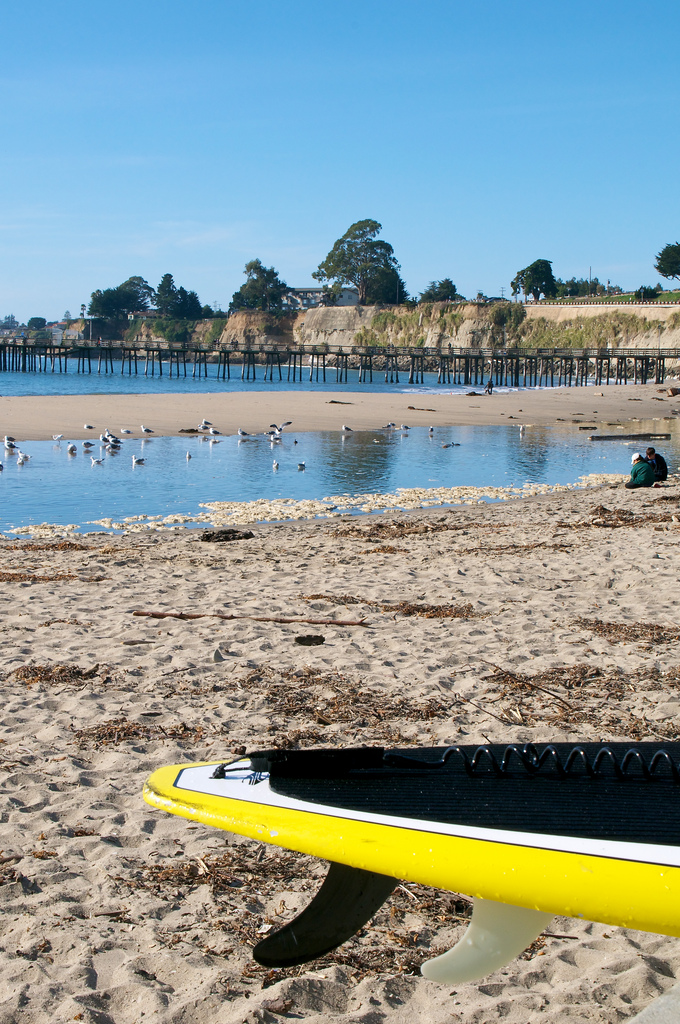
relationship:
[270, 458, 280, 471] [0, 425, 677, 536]
bird in pond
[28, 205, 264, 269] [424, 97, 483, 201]
clouds in sky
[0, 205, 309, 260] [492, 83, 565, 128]
clouds in sky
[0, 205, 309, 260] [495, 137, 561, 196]
clouds in sky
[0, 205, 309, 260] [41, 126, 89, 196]
clouds in sky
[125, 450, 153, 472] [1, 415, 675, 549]
bird in pond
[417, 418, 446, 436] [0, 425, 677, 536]
bird in pond